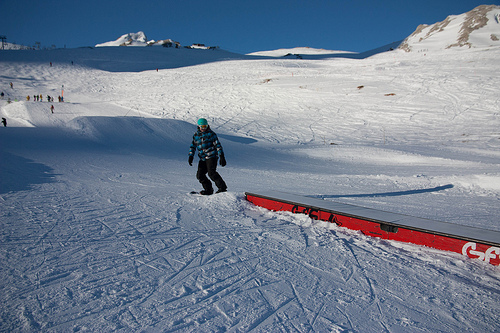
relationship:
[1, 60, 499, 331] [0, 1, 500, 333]
lines in snow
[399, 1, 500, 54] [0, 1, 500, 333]
mound in snow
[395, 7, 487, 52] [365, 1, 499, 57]
bare streaks on mountain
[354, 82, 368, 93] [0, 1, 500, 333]
spot in snow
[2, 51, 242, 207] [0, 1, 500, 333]
people on snow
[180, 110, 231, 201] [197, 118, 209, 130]
man wears aqua cap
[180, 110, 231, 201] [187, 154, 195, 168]
man wears glove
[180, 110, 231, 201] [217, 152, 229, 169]
man wears glove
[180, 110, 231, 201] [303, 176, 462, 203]
man has shadow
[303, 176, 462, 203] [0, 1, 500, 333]
shadow on snow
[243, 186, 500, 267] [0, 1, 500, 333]
ramp on snow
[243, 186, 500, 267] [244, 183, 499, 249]
ramp has edge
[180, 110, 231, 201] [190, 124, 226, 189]
man wears clothes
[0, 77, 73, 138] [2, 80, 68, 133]
people in crowd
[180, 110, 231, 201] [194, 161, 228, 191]
man wears pants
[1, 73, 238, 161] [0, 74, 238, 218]
jumps for snowboarders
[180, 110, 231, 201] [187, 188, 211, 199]
man on snowboard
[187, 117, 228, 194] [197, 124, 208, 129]
man wears goggles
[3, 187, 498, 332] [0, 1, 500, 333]
tracks in snow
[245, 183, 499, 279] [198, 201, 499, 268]
ramp half buried in snow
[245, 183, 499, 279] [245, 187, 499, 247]
ramp has surface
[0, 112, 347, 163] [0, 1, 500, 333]
shadow on snow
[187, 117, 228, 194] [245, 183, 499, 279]
man ready to use ramp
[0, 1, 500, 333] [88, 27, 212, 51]
snow on mountaintops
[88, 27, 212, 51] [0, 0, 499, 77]
mountaintops in distance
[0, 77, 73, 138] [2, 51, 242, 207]
people on slopes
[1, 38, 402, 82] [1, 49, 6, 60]
shadow of mountain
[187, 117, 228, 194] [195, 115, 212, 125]
man wears aqua cap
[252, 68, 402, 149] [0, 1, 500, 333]
earth patches in snow